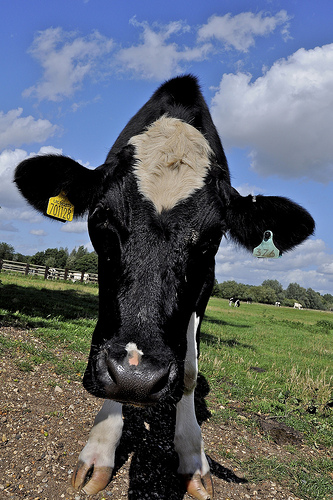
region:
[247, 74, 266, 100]
part of a cloiud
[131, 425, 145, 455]
part of a shade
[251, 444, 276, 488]
part of a ground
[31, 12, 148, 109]
this is the sky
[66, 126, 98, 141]
the sky is blue in color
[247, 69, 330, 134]
this is the cloud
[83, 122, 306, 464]
this is a cow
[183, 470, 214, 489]
this is the heels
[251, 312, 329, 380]
this is a grass area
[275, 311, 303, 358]
the grass is green in color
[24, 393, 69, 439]
this is a bare ground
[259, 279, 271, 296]
this is a tree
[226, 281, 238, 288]
the leaves are green in color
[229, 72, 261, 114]
part of a cloud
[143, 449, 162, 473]
part of a shade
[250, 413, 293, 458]
part of a ground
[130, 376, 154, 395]
part of a nose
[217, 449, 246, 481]
part of a shade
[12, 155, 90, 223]
yellow tag on cows ear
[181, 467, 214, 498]
brown houves of black and white cow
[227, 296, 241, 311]
black and white cow grazing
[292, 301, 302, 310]
white cow grazing behind black one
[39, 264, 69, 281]
wood picket fence in front of cow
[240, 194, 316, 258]
white tag on cows ear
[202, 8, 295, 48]
clouds in the sky above cow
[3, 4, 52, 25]
clear blue sky in the distance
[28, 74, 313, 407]
black and white cow looking at camera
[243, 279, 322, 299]
tree line in the distance behind cows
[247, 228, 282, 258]
the tag is blue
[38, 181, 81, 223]
the tag is yellow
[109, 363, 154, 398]
the nose is black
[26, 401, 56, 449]
the dirt is rocky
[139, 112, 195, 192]
the cow has a white spot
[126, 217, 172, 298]
the cow is black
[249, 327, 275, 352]
the grass is green in color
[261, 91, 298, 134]
the cloud id fluffy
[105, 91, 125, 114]
the sky is blue in color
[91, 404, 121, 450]
the leg is white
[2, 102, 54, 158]
White cloud in the sky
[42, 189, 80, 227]
Yellow tag in cows ear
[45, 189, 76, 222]
yellow tag with black numbers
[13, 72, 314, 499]
black and white cows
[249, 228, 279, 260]
blue tag with worn numbers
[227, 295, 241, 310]
cow grazing in a field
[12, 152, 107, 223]
black ear with a yellow tag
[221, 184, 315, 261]
black ear with a blue tag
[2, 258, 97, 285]
fence surrounding cows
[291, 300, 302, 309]
large white cow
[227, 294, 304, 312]
three cows grazing in the grass